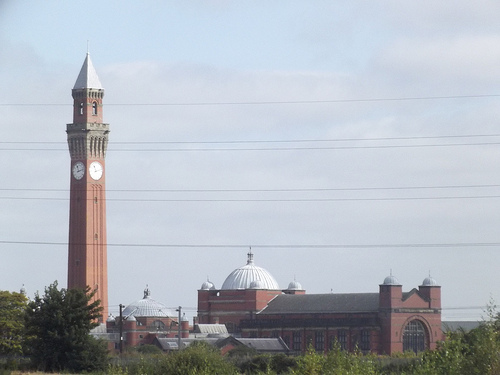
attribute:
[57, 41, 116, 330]
tower — tall, brick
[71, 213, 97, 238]
brick — red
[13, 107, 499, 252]
powerlines — black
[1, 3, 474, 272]
sky — overcast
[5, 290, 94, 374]
trees — green, leafy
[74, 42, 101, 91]
point — white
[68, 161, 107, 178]
two clocks — round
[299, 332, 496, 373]
bushes — green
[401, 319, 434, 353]
window — arched